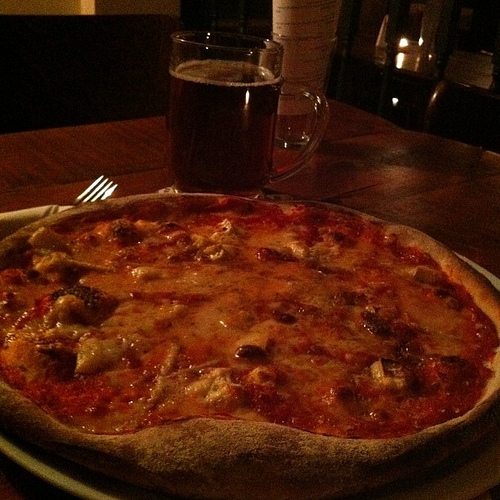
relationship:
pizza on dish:
[1, 175, 498, 500] [1, 188, 498, 499]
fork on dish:
[0, 169, 128, 253] [1, 188, 498, 499]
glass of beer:
[163, 17, 333, 205] [165, 56, 285, 204]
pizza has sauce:
[1, 175, 498, 500] [4, 203, 496, 435]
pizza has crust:
[1, 175, 498, 500] [0, 188, 499, 491]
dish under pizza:
[1, 188, 498, 499] [1, 175, 498, 500]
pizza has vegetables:
[1, 175, 498, 500] [30, 220, 423, 412]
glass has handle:
[163, 17, 333, 205] [263, 79, 331, 184]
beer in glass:
[165, 56, 285, 204] [163, 17, 333, 205]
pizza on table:
[1, 175, 498, 500] [0, 93, 498, 499]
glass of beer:
[163, 28, 328, 204] [165, 56, 285, 204]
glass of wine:
[163, 17, 333, 205] [158, 56, 290, 197]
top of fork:
[76, 172, 131, 213] [0, 169, 128, 253]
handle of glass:
[263, 79, 331, 184] [163, 28, 328, 204]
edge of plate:
[405, 234, 500, 309] [1, 175, 498, 500]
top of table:
[4, 96, 496, 297] [0, 93, 498, 499]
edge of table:
[0, 82, 268, 150] [0, 93, 498, 499]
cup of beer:
[163, 17, 333, 205] [165, 56, 285, 204]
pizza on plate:
[1, 175, 498, 500] [1, 175, 498, 500]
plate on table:
[1, 175, 498, 500] [0, 93, 498, 499]